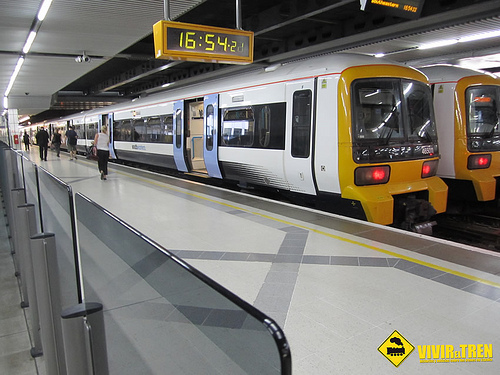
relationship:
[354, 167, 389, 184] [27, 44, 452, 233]
red ligth in back of train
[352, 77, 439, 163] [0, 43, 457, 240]
window on train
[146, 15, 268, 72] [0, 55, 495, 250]
sign hanging in train station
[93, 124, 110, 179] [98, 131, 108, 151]
woman has shirt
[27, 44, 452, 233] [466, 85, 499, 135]
train has window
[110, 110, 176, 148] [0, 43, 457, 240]
window on train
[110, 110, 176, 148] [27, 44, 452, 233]
window on train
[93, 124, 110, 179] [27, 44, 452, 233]
woman walking near train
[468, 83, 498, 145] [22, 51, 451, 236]
window on train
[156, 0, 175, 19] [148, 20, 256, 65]
pole holds up sign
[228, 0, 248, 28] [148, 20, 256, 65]
pole holds up sign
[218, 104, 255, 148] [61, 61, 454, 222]
window on a train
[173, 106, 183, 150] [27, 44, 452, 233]
window on train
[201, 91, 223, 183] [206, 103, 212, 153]
door with window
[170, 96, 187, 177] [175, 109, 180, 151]
door with window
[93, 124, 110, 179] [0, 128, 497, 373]
woman walking down platform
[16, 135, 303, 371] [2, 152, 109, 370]
glass panels and poles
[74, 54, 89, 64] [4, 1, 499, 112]
camera on ceiling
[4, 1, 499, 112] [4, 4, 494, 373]
ceiling on train station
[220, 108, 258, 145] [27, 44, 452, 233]
window on train